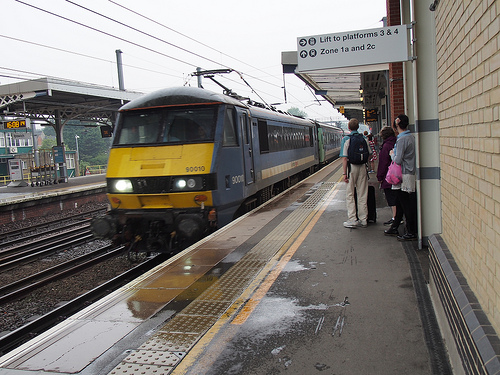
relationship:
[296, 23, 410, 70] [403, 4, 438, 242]
direction sign on post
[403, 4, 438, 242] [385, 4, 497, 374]
post near wall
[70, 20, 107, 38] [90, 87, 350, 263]
line on top of car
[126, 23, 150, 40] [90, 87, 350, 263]
line on top of car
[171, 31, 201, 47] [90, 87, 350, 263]
line on top of car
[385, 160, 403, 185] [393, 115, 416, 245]
bag carried by person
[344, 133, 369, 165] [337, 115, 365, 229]
backpack on back of person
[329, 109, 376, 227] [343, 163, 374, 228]
man wearing pants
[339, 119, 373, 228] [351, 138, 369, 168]
man wearing backpack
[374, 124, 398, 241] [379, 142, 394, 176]
lady has on purple shirt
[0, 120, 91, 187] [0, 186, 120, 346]
station across tracks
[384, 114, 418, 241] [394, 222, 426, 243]
person wearing shoe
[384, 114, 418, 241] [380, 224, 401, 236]
person wearing shoe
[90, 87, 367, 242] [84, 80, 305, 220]
car behind train engine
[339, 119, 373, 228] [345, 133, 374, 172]
man wearing backpack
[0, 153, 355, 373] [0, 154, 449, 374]
yellow line on platform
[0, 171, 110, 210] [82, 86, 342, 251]
platform left of train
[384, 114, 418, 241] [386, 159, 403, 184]
person carrying bag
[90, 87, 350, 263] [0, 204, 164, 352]
car on rail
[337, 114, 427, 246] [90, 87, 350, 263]
people waiting for car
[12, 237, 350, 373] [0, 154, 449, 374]
puddle on platform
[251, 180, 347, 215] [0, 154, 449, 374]
puddle on platform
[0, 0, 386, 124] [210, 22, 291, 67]
clouds in sky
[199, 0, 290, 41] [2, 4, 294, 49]
clouds in sky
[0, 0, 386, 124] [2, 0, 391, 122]
clouds in sky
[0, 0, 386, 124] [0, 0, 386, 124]
clouds in clouds